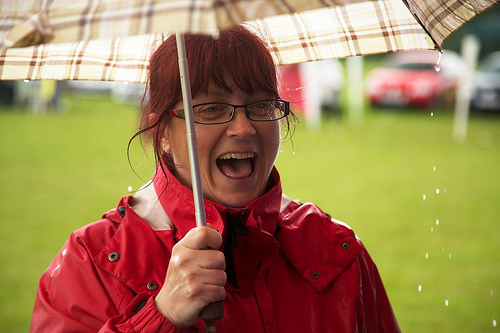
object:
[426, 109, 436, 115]
drop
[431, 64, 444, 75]
rain water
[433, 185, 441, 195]
drop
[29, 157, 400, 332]
coat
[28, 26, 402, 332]
woman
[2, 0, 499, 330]
umbrella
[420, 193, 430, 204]
rain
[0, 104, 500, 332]
grass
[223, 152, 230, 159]
teeth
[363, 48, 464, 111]
car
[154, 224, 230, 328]
hand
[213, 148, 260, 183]
mouth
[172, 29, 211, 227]
handle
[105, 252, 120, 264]
snap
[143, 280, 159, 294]
snap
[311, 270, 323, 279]
snap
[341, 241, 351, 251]
snap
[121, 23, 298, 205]
hair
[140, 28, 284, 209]
head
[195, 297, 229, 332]
handle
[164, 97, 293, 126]
glasses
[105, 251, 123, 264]
button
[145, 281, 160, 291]
button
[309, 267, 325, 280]
button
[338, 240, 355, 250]
button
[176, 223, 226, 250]
finger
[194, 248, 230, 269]
finger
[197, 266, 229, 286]
finger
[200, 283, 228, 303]
finger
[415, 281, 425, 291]
water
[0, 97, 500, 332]
ground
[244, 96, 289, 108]
glass rims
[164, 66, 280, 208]
face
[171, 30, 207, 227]
rod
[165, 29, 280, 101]
bangs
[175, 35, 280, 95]
forehead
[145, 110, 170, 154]
ear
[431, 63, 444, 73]
drop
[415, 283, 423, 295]
drop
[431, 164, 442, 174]
falling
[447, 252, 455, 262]
rain drop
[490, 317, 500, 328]
drop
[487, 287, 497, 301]
drop